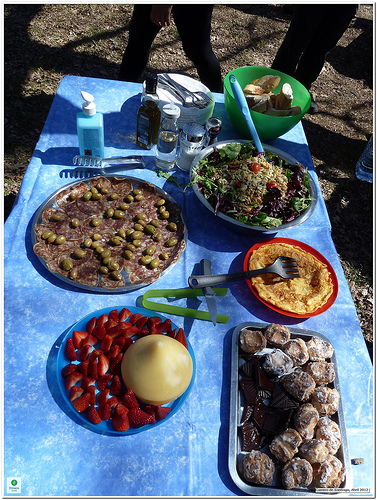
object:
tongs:
[137, 274, 231, 328]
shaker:
[204, 117, 222, 147]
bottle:
[176, 119, 210, 176]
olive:
[265, 184, 284, 211]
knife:
[228, 73, 265, 155]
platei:
[246, 240, 334, 317]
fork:
[186, 256, 300, 288]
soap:
[71, 89, 106, 161]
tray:
[269, 424, 302, 465]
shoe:
[355, 140, 373, 180]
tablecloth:
[0, 72, 374, 498]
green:
[141, 280, 229, 329]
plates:
[142, 73, 213, 118]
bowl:
[189, 136, 318, 238]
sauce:
[119, 331, 193, 409]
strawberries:
[96, 350, 110, 378]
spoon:
[227, 71, 278, 157]